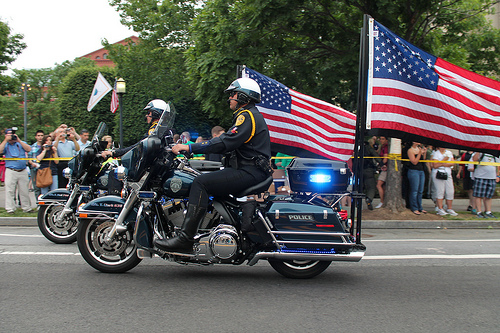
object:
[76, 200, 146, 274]
wheel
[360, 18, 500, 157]
flag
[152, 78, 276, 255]
cop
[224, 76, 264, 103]
helmet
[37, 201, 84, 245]
tire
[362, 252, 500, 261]
line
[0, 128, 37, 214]
man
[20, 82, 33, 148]
light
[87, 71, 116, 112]
flags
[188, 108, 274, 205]
uniform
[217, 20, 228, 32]
leaves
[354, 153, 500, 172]
tape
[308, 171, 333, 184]
light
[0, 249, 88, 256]
lines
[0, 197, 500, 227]
sidewalk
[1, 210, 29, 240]
corner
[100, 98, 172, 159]
men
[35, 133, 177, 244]
motorcycles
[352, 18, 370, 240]
pole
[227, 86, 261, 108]
head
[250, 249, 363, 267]
pipe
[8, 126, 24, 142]
camera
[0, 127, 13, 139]
hands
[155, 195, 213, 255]
boot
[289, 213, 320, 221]
logo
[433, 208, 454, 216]
shoes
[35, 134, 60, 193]
people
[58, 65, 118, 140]
trees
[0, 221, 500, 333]
road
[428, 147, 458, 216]
crowd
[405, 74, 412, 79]
stars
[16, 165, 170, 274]
front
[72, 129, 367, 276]
motorcycle